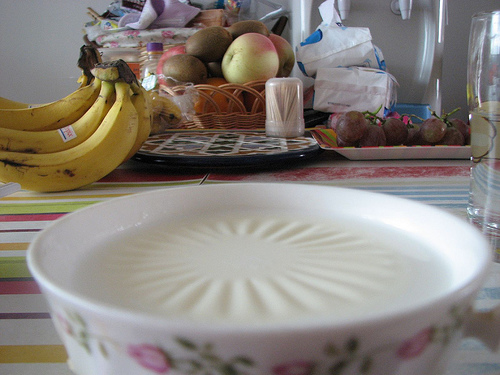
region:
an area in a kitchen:
[0, 14, 494, 373]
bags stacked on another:
[300, 22, 392, 112]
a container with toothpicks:
[262, 76, 308, 136]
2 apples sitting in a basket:
[221, 33, 291, 83]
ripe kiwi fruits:
[162, 27, 230, 82]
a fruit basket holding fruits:
[152, 82, 264, 130]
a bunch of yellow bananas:
[0, 64, 152, 189]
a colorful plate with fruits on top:
[315, 108, 467, 165]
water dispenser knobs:
[295, 0, 450, 27]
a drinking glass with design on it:
[464, 7, 497, 217]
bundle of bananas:
[0, 51, 150, 198]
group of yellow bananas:
[1, 53, 145, 188]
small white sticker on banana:
[55, 116, 82, 154]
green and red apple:
[213, 30, 287, 81]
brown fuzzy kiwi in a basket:
[176, 25, 236, 60]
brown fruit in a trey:
[386, 112, 446, 145]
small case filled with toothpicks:
[264, 73, 300, 128]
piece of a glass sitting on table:
[473, 13, 497, 223]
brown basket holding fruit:
[166, 79, 271, 131]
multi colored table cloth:
[8, 185, 56, 229]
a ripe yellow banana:
[0, 78, 130, 190]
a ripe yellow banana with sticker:
[3, 72, 111, 152]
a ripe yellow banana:
[0, 65, 106, 129]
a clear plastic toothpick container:
[264, 75, 301, 136]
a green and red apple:
[216, 30, 274, 85]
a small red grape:
[337, 107, 367, 142]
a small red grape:
[358, 120, 379, 145]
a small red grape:
[377, 113, 402, 143]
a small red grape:
[417, 115, 443, 146]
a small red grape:
[440, 124, 460, 143]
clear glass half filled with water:
[461, 8, 495, 251]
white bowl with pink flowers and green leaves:
[25, 179, 490, 372]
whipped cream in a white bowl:
[75, 199, 450, 310]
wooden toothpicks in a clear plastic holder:
[259, 74, 309, 137]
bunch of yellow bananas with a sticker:
[0, 59, 156, 196]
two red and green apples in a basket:
[223, 32, 296, 82]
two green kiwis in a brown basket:
[157, 26, 228, 81]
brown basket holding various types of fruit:
[151, 80, 267, 131]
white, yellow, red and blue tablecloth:
[1, 187, 41, 368]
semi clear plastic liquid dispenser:
[333, 0, 443, 111]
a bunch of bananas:
[0, 60, 152, 188]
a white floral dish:
[32, 180, 492, 373]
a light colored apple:
[219, 30, 279, 86]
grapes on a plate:
[310, 105, 470, 156]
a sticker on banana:
[57, 123, 77, 141]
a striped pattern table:
[0, 159, 497, 374]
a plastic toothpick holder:
[265, 75, 304, 138]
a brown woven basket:
[157, 77, 267, 129]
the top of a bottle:
[139, 38, 166, 88]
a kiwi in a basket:
[185, 25, 230, 61]